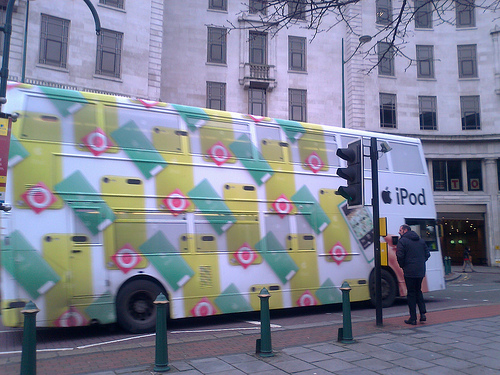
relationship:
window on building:
[420, 94, 438, 133] [4, 1, 499, 270]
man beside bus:
[396, 224, 431, 325] [0, 76, 449, 333]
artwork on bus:
[8, 80, 429, 325] [0, 76, 449, 333]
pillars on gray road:
[78, 291, 439, 363] [0, 265, 499, 375]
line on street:
[0, 318, 280, 356] [1, 275, 498, 362]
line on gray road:
[0, 318, 280, 356] [0, 265, 499, 375]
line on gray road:
[75, 333, 159, 352] [0, 265, 499, 375]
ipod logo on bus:
[381, 187, 428, 206] [0, 76, 449, 333]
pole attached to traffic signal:
[368, 135, 383, 327] [334, 134, 367, 209]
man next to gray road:
[396, 224, 431, 325] [0, 265, 499, 375]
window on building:
[398, 46, 498, 143] [4, 1, 499, 270]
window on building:
[458, 47, 483, 87] [4, 1, 499, 270]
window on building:
[324, 57, 482, 141] [4, 1, 499, 270]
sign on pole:
[321, 131, 366, 208] [367, 136, 387, 328]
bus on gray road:
[0, 76, 449, 333] [0, 265, 499, 375]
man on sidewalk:
[396, 224, 431, 325] [2, 308, 497, 373]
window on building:
[36, 10, 71, 70] [1, 0, 167, 102]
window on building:
[97, 27, 122, 78] [1, 0, 167, 102]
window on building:
[100, 0, 123, 14] [1, 0, 167, 102]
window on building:
[205, 26, 227, 65] [160, 0, 355, 131]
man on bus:
[396, 224, 431, 325] [0, 76, 449, 333]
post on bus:
[339, 278, 354, 342] [0, 76, 449, 333]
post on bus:
[253, 285, 273, 355] [0, 76, 449, 333]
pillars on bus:
[153, 292, 169, 373] [0, 76, 449, 333]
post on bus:
[16, 299, 39, 373] [0, 76, 449, 333]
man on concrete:
[391, 223, 432, 327] [412, 313, 494, 370]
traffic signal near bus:
[329, 137, 366, 209] [0, 76, 449, 333]